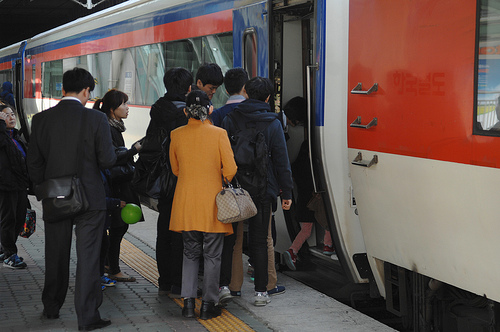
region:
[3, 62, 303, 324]
People are standing on a gray platform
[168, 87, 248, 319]
Woman with orange coat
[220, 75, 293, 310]
Man with a black backpack.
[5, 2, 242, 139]
Red and blue stripes on train.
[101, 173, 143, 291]
Child with a green ball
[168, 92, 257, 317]
Woman with a purse on her arm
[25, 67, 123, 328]
Man with black bag on back.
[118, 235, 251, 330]
A yellow stripe on platform.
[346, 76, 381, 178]
Metal hooks on side of train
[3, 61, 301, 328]
People waiting to board train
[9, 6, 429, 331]
group of people getting on a train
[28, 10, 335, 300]
a group of people standing on a sidewalk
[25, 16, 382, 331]
group of people on sidewalk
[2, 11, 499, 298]
a train at the station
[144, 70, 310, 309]
a women wearing a yellow jacket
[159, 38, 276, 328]
a woman holding a purse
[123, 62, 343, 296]
a woman holding a bag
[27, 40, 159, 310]
a man with a bag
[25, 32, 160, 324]
a man in a suit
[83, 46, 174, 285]
a woman with a ponytail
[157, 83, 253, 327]
person waiting to get on the train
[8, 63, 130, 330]
person waiting to get on the train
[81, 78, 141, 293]
person waiting to get on the train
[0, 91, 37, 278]
person waiting to get on the train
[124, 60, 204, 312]
person waiting to get on the train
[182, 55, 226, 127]
person waiting to get on the train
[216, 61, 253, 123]
person waiting to get on the train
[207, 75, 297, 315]
person waiting to get on the train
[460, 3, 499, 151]
window of a train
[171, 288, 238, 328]
pair of black shoes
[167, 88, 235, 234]
woman in a yellow coat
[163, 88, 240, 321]
woman in a yellow coat getting ready to board a train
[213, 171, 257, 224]
brown and white handbag held by the woman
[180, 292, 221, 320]
black shoes on the woman's feet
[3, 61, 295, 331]
group of people on a train platform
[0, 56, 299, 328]
group of people preparing to board the train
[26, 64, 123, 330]
men in a suite looking downward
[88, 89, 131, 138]
woman wearing a ponytail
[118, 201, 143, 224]
green ball in the woman's hand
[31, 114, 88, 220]
black bag across the man's back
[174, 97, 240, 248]
woman wearing yellow jacket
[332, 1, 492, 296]
white and red train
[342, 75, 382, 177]
three handles on train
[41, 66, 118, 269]
man wearing black suit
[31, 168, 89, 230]
small black laptop bag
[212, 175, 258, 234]
small tan handbag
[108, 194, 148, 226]
round green ball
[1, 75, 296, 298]
group of people in a line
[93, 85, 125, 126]
woman with black hair in ponytail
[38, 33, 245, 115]
windows of a train